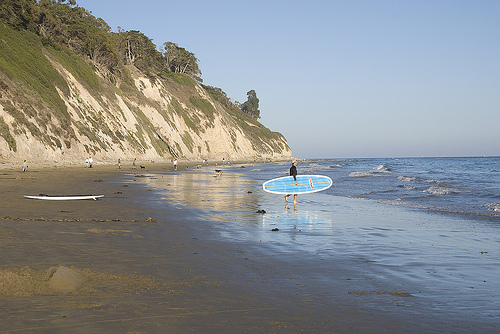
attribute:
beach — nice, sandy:
[9, 167, 494, 332]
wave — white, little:
[349, 160, 390, 177]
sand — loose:
[6, 259, 123, 301]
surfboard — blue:
[261, 174, 333, 194]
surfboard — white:
[21, 187, 108, 213]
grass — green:
[10, 9, 306, 197]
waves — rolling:
[332, 154, 496, 219]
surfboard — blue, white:
[256, 175, 338, 196]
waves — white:
[363, 163, 442, 207]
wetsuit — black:
[287, 167, 299, 180]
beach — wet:
[338, 278, 410, 299]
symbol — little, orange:
[308, 175, 316, 190]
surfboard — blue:
[257, 172, 334, 197]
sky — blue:
[74, 3, 498, 163]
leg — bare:
[291, 192, 298, 211]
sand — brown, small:
[42, 247, 158, 290]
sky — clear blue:
[237, 20, 362, 93]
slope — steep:
[214, 103, 290, 160]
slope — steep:
[200, 83, 290, 157]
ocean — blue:
[227, 157, 499, 227]